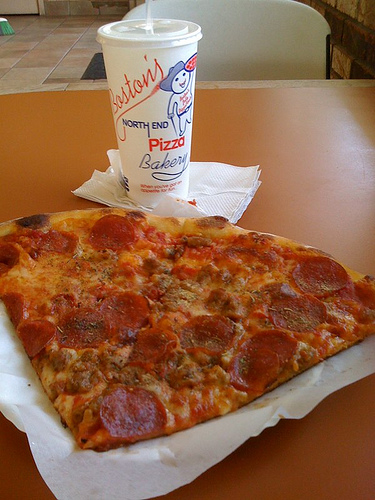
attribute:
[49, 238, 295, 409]
pizza — slices, pepperoni, slice, red, cooked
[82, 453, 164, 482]
paper — greasy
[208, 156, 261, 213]
napkin — white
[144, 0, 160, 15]
straw — clear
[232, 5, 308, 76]
chair — white, plastic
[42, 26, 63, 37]
floor — brown, tile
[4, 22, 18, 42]
broom — green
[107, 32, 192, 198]
cup — paper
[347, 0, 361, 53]
wall — brick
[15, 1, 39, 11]
door — tile